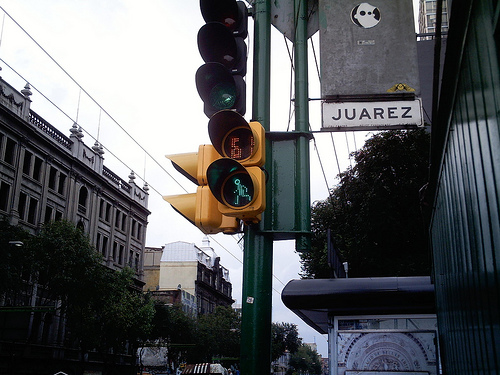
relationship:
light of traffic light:
[211, 114, 259, 159] [163, 106, 267, 233]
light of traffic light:
[174, 90, 365, 265] [159, 111, 287, 227]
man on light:
[259, 330, 331, 374] [183, 132, 255, 219]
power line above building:
[34, 42, 139, 155] [3, 80, 148, 295]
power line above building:
[34, 84, 120, 154] [3, 80, 148, 295]